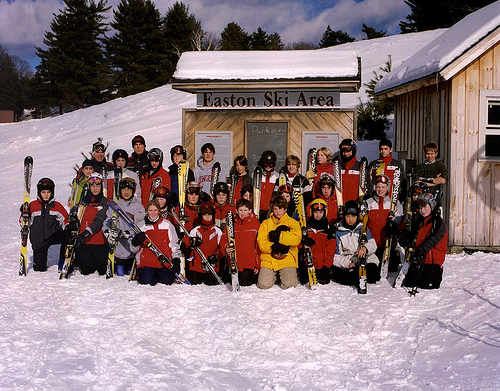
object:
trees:
[396, 0, 500, 37]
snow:
[0, 27, 499, 391]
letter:
[222, 96, 231, 108]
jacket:
[255, 212, 303, 273]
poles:
[169, 206, 226, 288]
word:
[295, 88, 336, 107]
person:
[190, 141, 223, 200]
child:
[394, 190, 450, 292]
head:
[421, 139, 439, 165]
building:
[169, 47, 363, 183]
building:
[371, 0, 500, 256]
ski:
[223, 209, 243, 294]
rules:
[193, 128, 234, 183]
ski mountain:
[1, 22, 451, 245]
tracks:
[1, 25, 500, 390]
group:
[17, 132, 449, 289]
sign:
[194, 88, 342, 108]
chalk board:
[242, 118, 289, 179]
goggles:
[374, 174, 390, 184]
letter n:
[246, 96, 258, 108]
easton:
[202, 90, 258, 107]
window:
[483, 133, 500, 157]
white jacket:
[330, 219, 381, 271]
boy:
[218, 197, 262, 288]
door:
[243, 119, 290, 178]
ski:
[259, 90, 289, 109]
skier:
[330, 199, 381, 286]